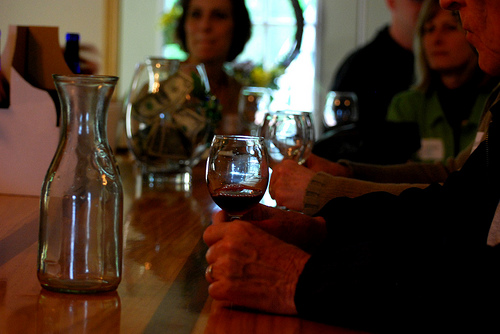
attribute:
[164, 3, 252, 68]
lady — content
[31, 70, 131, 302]
vase — empty, glass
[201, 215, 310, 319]
man's hand — wrinkled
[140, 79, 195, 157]
money — displayed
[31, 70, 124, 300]
pitcher — empty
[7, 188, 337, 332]
table — dark, striped, wood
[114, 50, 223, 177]
jar — glass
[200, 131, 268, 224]
wine glass — filled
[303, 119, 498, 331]
shirt — black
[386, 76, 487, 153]
shirt — green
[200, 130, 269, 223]
glass — clear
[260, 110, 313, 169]
glass — clear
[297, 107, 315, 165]
glass — clear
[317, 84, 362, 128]
glass — clear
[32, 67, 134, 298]
pitcher — clear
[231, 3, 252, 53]
hair — black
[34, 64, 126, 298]
bottle — clear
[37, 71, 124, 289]
bottle — glassy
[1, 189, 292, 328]
surface — wooden, glossy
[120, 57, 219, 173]
jar — clear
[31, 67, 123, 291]
glass — clear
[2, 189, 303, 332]
counter — wooden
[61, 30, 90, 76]
bottle — blue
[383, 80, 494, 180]
jacket — green